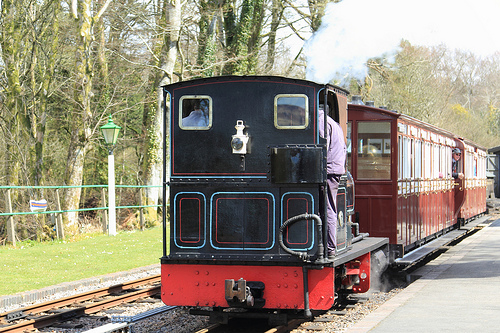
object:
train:
[144, 70, 376, 313]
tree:
[58, 0, 108, 235]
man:
[318, 102, 345, 260]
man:
[182, 98, 208, 127]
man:
[299, 98, 356, 267]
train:
[131, 68, 500, 317]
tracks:
[10, 294, 160, 332]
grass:
[7, 241, 138, 277]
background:
[5, 71, 148, 265]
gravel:
[146, 319, 196, 330]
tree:
[203, 8, 255, 69]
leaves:
[235, 11, 251, 21]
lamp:
[91, 108, 130, 238]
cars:
[345, 100, 460, 271]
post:
[95, 111, 123, 239]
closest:
[106, 57, 475, 323]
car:
[449, 137, 493, 231]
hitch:
[222, 274, 258, 311]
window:
[175, 88, 214, 138]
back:
[314, 116, 352, 181]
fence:
[9, 178, 94, 245]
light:
[227, 116, 259, 159]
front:
[167, 82, 322, 278]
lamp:
[93, 108, 132, 155]